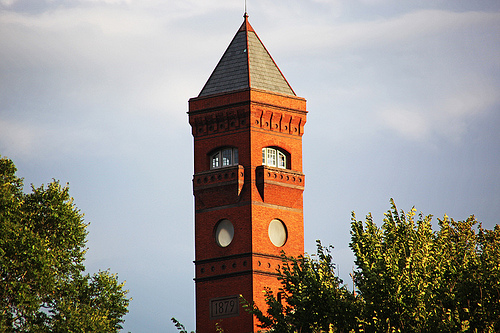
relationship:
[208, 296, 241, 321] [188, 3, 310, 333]
number on tower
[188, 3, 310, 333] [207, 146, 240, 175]
tower has window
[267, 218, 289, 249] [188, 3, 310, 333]
circle on tower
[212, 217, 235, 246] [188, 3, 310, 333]
circle on tower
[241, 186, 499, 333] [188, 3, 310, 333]
tree below tower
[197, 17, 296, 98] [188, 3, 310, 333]
roof on tower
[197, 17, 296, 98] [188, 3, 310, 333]
roof on top of tower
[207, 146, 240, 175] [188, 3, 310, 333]
window on tower